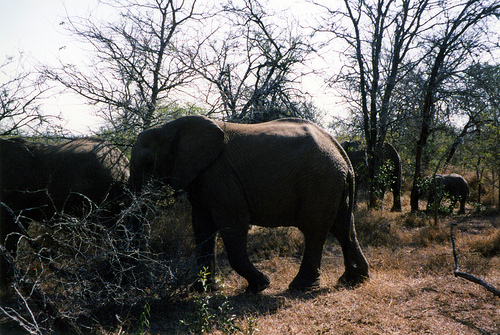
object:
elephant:
[126, 113, 372, 295]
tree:
[37, 0, 237, 131]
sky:
[0, 1, 500, 138]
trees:
[421, 62, 500, 206]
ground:
[0, 128, 500, 334]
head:
[127, 113, 230, 194]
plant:
[185, 264, 217, 334]